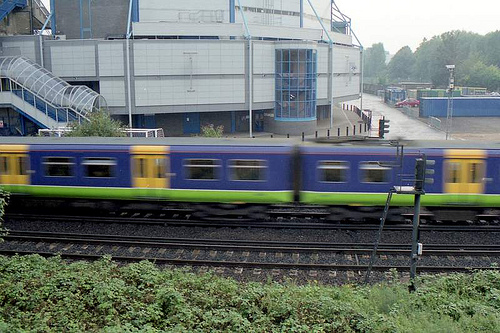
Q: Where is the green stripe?
A: On the bottom of the train.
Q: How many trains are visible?
A: One.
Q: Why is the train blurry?
A: It is moving fast.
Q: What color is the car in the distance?
A: Red.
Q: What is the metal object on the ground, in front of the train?
A: A second set of tracks.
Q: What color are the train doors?
A: Yellow.